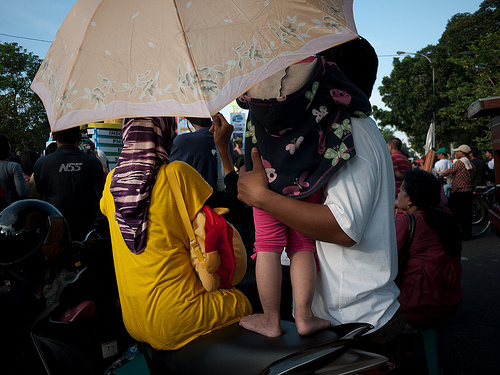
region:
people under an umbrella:
[40, 1, 407, 308]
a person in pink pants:
[248, 190, 324, 254]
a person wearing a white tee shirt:
[315, 107, 406, 321]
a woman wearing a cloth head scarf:
[105, 118, 179, 251]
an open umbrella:
[43, 2, 351, 133]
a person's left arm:
[264, 151, 360, 262]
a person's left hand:
[232, 151, 266, 217]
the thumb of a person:
[242, 143, 262, 170]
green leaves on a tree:
[450, 33, 491, 95]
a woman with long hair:
[400, 165, 460, 247]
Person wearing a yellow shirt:
[85, 148, 242, 338]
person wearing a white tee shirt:
[328, 116, 402, 373]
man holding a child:
[237, 96, 337, 255]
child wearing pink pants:
[238, 173, 318, 254]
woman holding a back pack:
[158, 158, 247, 286]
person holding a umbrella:
[21, 13, 265, 170]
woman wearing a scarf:
[96, 98, 175, 260]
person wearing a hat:
[448, 135, 475, 160]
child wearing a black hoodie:
[248, 80, 345, 200]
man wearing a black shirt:
[26, 143, 108, 201]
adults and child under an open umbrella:
[25, 7, 405, 355]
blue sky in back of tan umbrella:
[0, 1, 490, 148]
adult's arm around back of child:
[230, 36, 390, 342]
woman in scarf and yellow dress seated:
[95, 117, 252, 347]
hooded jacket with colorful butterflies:
[236, 55, 351, 200]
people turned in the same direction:
[381, 97, 496, 229]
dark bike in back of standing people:
[1, 111, 121, 367]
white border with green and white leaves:
[31, 0, 356, 130]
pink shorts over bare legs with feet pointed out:
[235, 200, 330, 336]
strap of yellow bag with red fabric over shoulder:
[161, 160, 248, 291]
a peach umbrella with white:
[46, 5, 346, 142]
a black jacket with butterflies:
[246, 88, 363, 203]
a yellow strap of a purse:
[160, 143, 239, 300]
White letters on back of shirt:
[44, 151, 104, 186]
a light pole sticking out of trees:
[379, 27, 453, 123]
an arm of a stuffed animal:
[178, 193, 247, 285]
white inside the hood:
[239, 62, 301, 98]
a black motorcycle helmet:
[1, 175, 85, 285]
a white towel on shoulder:
[450, 153, 486, 186]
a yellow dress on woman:
[99, 143, 270, 343]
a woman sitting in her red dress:
[394, 168, 470, 374]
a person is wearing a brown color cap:
[441, 146, 476, 238]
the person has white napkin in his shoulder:
[436, 144, 474, 244]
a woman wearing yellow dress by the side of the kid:
[99, 26, 351, 348]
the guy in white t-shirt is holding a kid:
[237, 34, 406, 372]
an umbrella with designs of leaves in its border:
[30, 15, 350, 130]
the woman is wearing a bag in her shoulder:
[101, 116, 248, 344]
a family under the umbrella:
[33, 3, 401, 363]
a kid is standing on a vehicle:
[233, 21, 343, 372]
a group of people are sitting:
[6, 96, 465, 361]